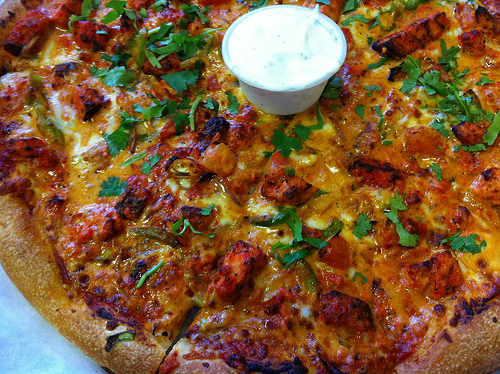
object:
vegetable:
[103, 319, 133, 357]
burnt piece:
[197, 112, 229, 152]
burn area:
[222, 355, 311, 372]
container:
[219, 3, 349, 117]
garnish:
[380, 189, 421, 249]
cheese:
[39, 9, 499, 282]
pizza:
[0, 0, 498, 372]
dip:
[230, 7, 330, 84]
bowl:
[219, 4, 349, 119]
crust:
[0, 195, 499, 372]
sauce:
[204, 242, 275, 305]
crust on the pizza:
[8, 240, 80, 333]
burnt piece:
[370, 15, 448, 62]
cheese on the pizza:
[40, 60, 132, 173]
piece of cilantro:
[346, 154, 406, 194]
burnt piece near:
[190, 104, 233, 154]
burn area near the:
[246, 356, 307, 372]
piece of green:
[402, 48, 496, 137]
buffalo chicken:
[354, 155, 403, 198]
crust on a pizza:
[61, 319, 145, 372]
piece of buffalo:
[3, 73, 82, 130]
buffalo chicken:
[135, 36, 199, 89]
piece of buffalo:
[205, 231, 263, 302]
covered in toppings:
[383, 103, 473, 253]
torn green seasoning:
[262, 212, 322, 279]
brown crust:
[6, 221, 78, 326]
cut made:
[146, 311, 208, 347]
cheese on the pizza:
[200, 183, 292, 235]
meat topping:
[285, 277, 392, 341]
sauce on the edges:
[222, 4, 344, 95]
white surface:
[10, 314, 65, 370]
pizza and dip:
[0, 0, 500, 374]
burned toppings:
[357, 25, 438, 98]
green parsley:
[263, 203, 341, 265]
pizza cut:
[140, 268, 217, 365]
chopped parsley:
[104, 11, 211, 128]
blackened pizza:
[227, 343, 273, 373]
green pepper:
[125, 223, 177, 256]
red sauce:
[446, 145, 484, 187]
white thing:
[70, 361, 100, 373]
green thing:
[289, 257, 324, 306]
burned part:
[92, 298, 164, 353]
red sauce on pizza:
[8, 137, 74, 212]